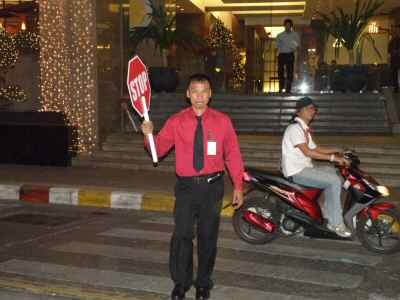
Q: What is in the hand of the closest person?
A: Stop sign.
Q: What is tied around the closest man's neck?
A: Tie.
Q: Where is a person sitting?
A: On a motorcycle.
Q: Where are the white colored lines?
A: On the pavement.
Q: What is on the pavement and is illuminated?
A: Headlight.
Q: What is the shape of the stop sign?
A: Octagon.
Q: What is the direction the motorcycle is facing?
A: Right.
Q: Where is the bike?
A: Behind the man in red.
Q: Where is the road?
A: Under the bike.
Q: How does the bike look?
A: Red.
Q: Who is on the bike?
A: The biker.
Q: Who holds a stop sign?
A: The man in red.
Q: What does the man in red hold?
A: A stop sign.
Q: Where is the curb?
A: Behind the bike.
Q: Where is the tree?
A: By the doors.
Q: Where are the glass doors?
A: By the trees.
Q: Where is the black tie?
A: Over the red shirt.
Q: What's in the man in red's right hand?
A: A stop sign.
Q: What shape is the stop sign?
A: Octagon.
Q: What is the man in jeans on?
A: A scooter.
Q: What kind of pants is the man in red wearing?
A: Slacks.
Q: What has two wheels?
A: A scooter.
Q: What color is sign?
A: Red.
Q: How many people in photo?
A: 3.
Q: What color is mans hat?
A: Black.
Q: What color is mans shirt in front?
A: Red.